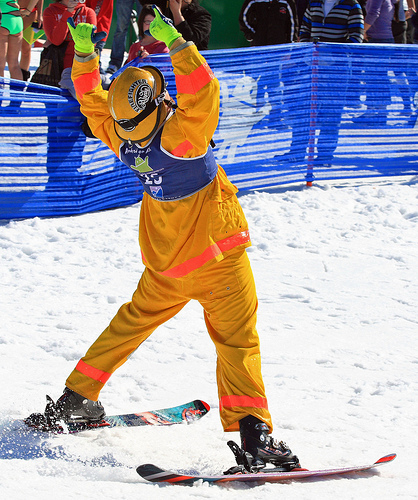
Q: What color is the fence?
A: Blue.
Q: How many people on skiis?
A: One.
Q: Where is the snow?
A: On the ground.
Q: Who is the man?
A: A fireman.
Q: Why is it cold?
A: Its wintertime.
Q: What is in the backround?
A: People.